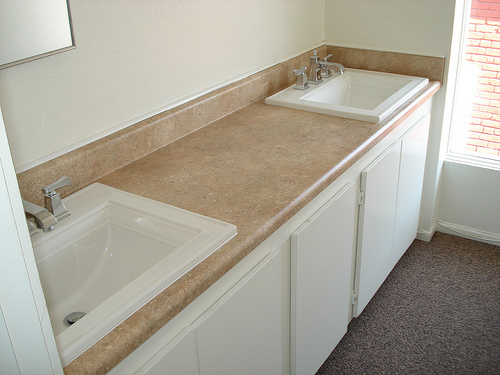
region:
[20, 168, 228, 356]
this is a sink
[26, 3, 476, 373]
a double sink vanity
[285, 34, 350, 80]
faucet on the sink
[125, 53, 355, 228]
a light brown countertop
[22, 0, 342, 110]
white wall above counter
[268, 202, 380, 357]
a white cabinet door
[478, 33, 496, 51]
pink lines on wall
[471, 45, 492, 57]
white bricks on the wall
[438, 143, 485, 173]
white paint on the window ledge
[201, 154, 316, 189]
brown artisan stone on the counter top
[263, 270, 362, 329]
white color on the counter doors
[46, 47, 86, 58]
silver edge on mirror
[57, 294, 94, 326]
silver stopper in sink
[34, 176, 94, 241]
silver faucet on top of sink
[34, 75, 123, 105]
gray paint on the wall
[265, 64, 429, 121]
a white porcelain bathroom sink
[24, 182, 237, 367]
a white porcelain bathroom sink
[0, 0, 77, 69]
a wall mounted vanity mirror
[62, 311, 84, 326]
a chrome sink drain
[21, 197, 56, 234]
a chrome bathroom sink faucet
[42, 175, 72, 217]
a chrome faucet handle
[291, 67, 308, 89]
a chrome faucet handle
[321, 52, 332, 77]
a chrome faucet handle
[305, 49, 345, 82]
a chrome bathroom sink faucet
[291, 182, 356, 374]
a white cabinet door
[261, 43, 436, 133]
White sink is near the wall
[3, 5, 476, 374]
Room has 2 sinks next to each other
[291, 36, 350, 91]
Silver faucets are above the sinks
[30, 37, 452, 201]
Counter top has a backsplash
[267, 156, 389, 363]
White cupboard doors are underneath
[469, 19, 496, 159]
Brick wall is seen through the window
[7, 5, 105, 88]
Mirror is hanging over the sink on the left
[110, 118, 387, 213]
Counter is a brownish color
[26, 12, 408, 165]
Wall is painted in an off white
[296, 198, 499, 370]
Carpet on the floor is plush and nice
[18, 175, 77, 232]
Chrome faucet on bathroom sink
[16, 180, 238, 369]
Square white sink in bathroom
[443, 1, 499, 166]
Brick wall outside bathroom window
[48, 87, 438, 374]
White cabinets under sink in bathroom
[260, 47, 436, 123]
Sink on a counter.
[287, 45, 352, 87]
Silver faucet on a sink.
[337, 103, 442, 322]
White cupboard in a bathroom.